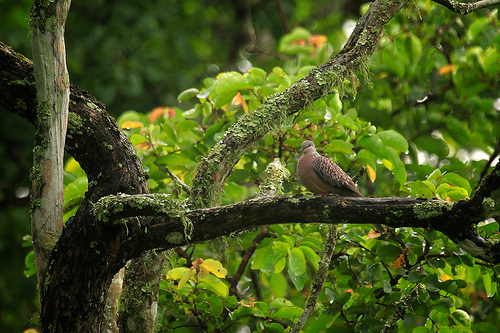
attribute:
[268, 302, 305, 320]
leaf — green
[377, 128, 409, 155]
leaf — green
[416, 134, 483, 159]
gap — white, area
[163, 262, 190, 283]
leaf — green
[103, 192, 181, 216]
nest — green, bird's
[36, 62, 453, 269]
tree — with gap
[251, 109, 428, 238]
bird — gray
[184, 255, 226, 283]
leaf — green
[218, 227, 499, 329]
branches — couple, thin, gray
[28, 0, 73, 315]
tree trunk — gray, tree's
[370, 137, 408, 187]
leaf — green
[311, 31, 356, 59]
leaf — orange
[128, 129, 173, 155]
yellow leaves — several, orange and yellow, green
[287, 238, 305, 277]
leaf — green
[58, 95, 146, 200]
trunk — curved, black, tree's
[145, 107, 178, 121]
leaf — red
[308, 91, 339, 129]
drop — water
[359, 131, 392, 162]
leaf — green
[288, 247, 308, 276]
leaf — green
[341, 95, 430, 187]
leaf — green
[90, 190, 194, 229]
stuff — green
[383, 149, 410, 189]
leaf — green